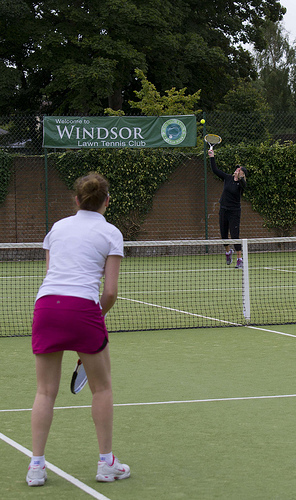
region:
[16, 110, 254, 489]
two women playing tennis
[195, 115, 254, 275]
a woman serving a tennis ball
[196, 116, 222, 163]
a racket about to hit the ball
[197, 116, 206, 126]
a yellow tennis ball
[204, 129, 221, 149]
a yellow and white tennis racket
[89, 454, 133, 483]
a pink and white tennis shoe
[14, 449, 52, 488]
a pink and white tennis shoe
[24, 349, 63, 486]
the leg of a woman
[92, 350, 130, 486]
the leg of a woman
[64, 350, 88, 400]
the head of a tennis racket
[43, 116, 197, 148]
green banner on the fence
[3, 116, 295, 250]
a tall green fence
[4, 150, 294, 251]
a brick wall covered in ivy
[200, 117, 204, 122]
a yellow tennis ball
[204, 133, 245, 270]
woman in black serving the tennis ball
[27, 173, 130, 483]
woman with a pink skirt playing tennis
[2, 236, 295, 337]
net in on the tennis court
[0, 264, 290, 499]
tennis court with white lines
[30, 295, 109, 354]
pink skirt on the tennis player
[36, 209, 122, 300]
white tennis shirt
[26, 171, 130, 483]
Woman playing tennis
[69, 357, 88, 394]
Racket in the woman's hand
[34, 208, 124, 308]
White shirt on the woman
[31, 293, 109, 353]
Shorts on the woman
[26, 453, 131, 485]
Shoes on the woman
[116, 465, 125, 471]
Nike logo on the woman's shoe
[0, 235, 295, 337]
Net on the tennis court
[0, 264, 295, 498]
White lines on the tennis court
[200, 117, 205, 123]
Tennis ball in the air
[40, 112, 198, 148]
Banner on the poles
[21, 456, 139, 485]
Girl wearing shoes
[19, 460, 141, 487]
Girl is wearing shoes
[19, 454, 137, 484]
Girl wearing white and pink shoes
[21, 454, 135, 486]
Girl is wearing white and pink shoes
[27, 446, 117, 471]
Girl wearing socks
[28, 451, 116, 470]
Girl is wearing socks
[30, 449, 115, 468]
Girl wearing white socks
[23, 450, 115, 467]
Girl is wearing white socks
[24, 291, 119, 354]
Girl wearing a pink skirt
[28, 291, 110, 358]
Girl is wearing a pink skirt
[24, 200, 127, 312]
woman wearing white shirt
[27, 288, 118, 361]
woman wearing pink skirt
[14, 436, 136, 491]
woman wearing white shoes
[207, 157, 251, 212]
woman wearing black shirt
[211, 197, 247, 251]
woman wearing black pants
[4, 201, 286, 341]
black and white tennis net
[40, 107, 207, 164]
green and white sign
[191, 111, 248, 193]
woman holding tennis racket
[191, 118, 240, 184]
woman has arm extended